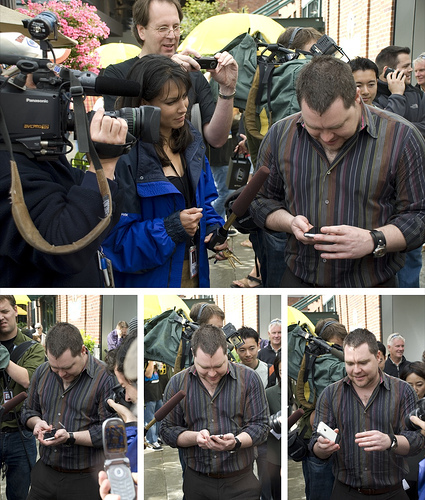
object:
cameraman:
[221, 22, 350, 131]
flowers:
[54, 0, 110, 77]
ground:
[362, 131, 402, 181]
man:
[99, 0, 238, 148]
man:
[2, 68, 126, 287]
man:
[21, 322, 119, 498]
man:
[0, 295, 44, 498]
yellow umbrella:
[87, 40, 142, 69]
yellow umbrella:
[143, 295, 194, 323]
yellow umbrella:
[288, 305, 317, 337]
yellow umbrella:
[11, 294, 31, 307]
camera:
[190, 55, 219, 71]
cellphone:
[102, 415, 135, 499]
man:
[15, 320, 130, 499]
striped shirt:
[20, 353, 125, 467]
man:
[373, 44, 424, 134]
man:
[106, 4, 244, 133]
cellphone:
[379, 66, 404, 83]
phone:
[303, 223, 334, 238]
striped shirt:
[306, 371, 425, 491]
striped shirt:
[154, 364, 271, 467]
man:
[234, 57, 424, 287]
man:
[309, 328, 421, 490]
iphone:
[312, 419, 338, 444]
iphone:
[209, 433, 225, 443]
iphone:
[42, 427, 57, 442]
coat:
[97, 115, 230, 286]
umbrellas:
[168, 11, 285, 66]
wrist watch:
[368, 226, 388, 259]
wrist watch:
[385, 430, 397, 453]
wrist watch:
[226, 435, 243, 457]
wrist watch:
[61, 430, 76, 447]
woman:
[101, 54, 228, 288]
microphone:
[205, 163, 271, 253]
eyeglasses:
[148, 23, 184, 38]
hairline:
[193, 345, 225, 359]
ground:
[184, 227, 276, 290]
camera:
[0, 10, 162, 160]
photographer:
[0, 43, 130, 290]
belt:
[336, 477, 401, 489]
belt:
[186, 463, 253, 476]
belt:
[42, 459, 103, 474]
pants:
[331, 482, 410, 498]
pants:
[182, 465, 262, 497]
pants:
[27, 458, 105, 498]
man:
[414, 49, 424, 92]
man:
[384, 331, 409, 374]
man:
[256, 316, 280, 362]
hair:
[386, 332, 405, 346]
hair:
[268, 318, 281, 334]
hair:
[412, 52, 425, 69]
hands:
[202, 432, 237, 452]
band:
[386, 432, 399, 453]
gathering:
[346, 44, 425, 286]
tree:
[5, 0, 109, 78]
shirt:
[244, 101, 425, 287]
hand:
[84, 111, 130, 165]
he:
[158, 322, 271, 498]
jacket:
[122, 419, 137, 471]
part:
[89, 70, 115, 97]